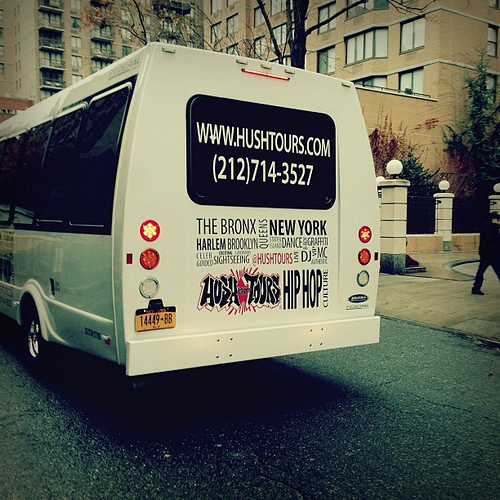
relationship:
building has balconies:
[25, 9, 118, 72] [40, 46, 78, 75]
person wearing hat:
[468, 212, 498, 292] [484, 216, 498, 223]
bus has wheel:
[102, 41, 403, 386] [21, 289, 55, 369]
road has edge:
[224, 429, 342, 481] [449, 319, 478, 345]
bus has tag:
[102, 41, 403, 386] [126, 286, 182, 334]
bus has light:
[102, 41, 403, 386] [135, 269, 171, 301]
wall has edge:
[389, 96, 419, 122] [408, 82, 441, 107]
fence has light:
[404, 192, 437, 233] [411, 167, 462, 194]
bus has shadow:
[102, 41, 403, 386] [202, 369, 276, 458]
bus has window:
[102, 41, 403, 386] [37, 105, 119, 229]